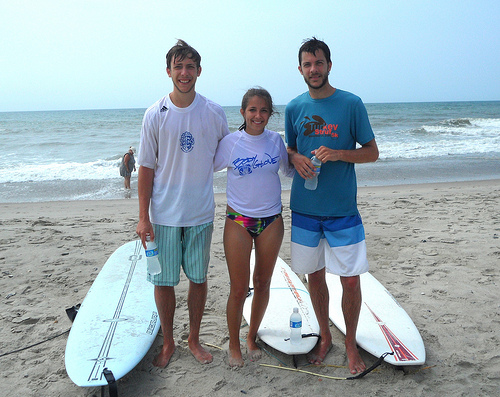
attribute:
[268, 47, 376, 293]
man — bare footed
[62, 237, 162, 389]
board — white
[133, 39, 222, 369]
man — bare footed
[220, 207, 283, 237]
bottom — bikini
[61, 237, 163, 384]
surfig board — blue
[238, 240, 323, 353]
surfig board — blue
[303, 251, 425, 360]
surfig board — blue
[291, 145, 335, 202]
bottle — water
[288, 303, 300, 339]
bottle — water